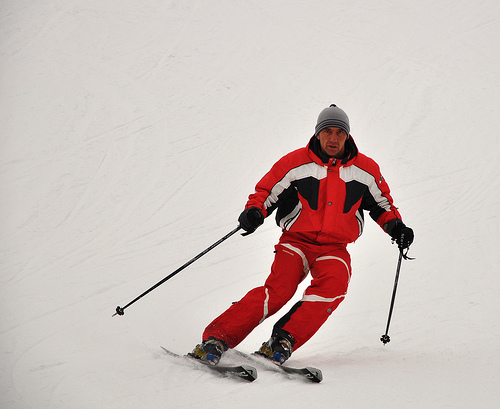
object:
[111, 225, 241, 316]
pole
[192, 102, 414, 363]
man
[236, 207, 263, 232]
hand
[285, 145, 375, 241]
jacket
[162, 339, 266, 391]
ski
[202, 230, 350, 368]
pants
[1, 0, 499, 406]
snow